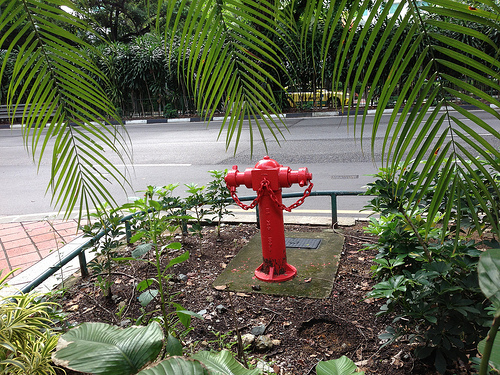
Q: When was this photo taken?
A: Daytime.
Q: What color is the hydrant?
A: Red.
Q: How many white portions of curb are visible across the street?
A: Eleven.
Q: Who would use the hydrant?
A: Firefighters.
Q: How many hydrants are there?
A: One.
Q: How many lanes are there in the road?
A: Four.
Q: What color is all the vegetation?
A: Green.